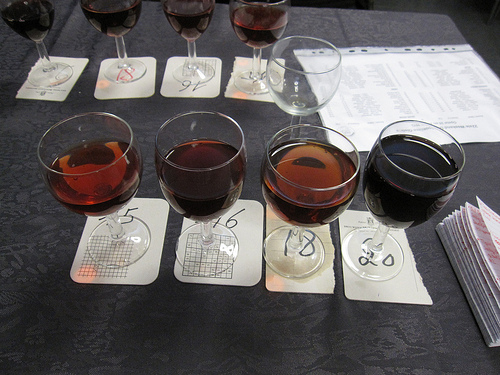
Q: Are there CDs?
A: No, there are no cds.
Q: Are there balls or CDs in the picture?
A: No, there are no CDs or balls.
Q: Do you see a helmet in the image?
A: No, there are no helmets.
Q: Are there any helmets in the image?
A: No, there are no helmets.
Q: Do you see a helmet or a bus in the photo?
A: No, there are no helmets or buses.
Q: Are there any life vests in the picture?
A: No, there are no life vests.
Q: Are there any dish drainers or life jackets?
A: No, there are no life jackets or dish drainers.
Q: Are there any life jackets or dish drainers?
A: No, there are no life jackets or dish drainers.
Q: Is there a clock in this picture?
A: No, there are no clocks.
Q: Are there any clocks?
A: No, there are no clocks.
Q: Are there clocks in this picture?
A: No, there are no clocks.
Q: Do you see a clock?
A: No, there are no clocks.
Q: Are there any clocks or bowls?
A: No, there are no clocks or bowls.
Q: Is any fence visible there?
A: No, there are no fences.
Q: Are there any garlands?
A: No, there are no garlands.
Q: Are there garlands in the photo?
A: No, there are no garlands.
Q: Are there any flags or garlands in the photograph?
A: No, there are no garlands or flags.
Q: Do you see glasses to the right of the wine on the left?
A: Yes, there are glasses to the right of the wine.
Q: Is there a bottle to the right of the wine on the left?
A: No, there are glasses to the right of the wine.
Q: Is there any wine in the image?
A: Yes, there is wine.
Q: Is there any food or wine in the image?
A: Yes, there is wine.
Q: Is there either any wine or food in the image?
A: Yes, there is wine.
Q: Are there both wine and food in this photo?
A: No, there is wine but no food.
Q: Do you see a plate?
A: No, there are no plates.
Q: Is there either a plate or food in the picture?
A: No, there are no plates or food.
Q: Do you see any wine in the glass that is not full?
A: Yes, there is wine in the glass.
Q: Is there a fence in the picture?
A: No, there are no fences.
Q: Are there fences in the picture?
A: No, there are no fences.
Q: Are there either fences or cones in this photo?
A: No, there are no fences or cones.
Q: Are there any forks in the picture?
A: No, there are no forks.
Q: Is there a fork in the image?
A: No, there are no forks.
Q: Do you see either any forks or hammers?
A: No, there are no forks or hammers.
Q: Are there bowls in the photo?
A: No, there are no bowls.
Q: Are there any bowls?
A: No, there are no bowls.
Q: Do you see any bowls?
A: No, there are no bowls.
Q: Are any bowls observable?
A: No, there are no bowls.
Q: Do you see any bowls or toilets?
A: No, there are no bowls or toilets.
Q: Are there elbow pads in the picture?
A: No, there are no elbow pads.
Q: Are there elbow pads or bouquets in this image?
A: No, there are no elbow pads or bouquets.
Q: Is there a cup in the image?
A: No, there are no cups.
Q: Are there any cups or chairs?
A: No, there are no cups or chairs.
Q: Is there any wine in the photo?
A: Yes, there is wine.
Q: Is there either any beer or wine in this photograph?
A: Yes, there is wine.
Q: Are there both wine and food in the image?
A: No, there is wine but no food.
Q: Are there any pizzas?
A: No, there are no pizzas.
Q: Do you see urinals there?
A: No, there are no urinals.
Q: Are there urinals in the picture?
A: No, there are no urinals.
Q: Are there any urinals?
A: No, there are no urinals.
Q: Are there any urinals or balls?
A: No, there are no urinals or balls.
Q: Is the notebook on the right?
A: Yes, the notebook is on the right of the image.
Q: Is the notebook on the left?
A: No, the notebook is on the right of the image.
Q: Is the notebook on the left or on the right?
A: The notebook is on the right of the image.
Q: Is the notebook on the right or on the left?
A: The notebook is on the right of the image.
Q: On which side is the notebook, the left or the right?
A: The notebook is on the right of the image.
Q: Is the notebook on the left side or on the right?
A: The notebook is on the right of the image.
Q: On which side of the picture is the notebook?
A: The notebook is on the right of the image.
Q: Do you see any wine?
A: Yes, there is wine.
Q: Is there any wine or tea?
A: Yes, there is wine.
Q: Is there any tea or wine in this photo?
A: Yes, there is wine.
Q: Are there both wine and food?
A: No, there is wine but no food.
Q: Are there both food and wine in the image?
A: No, there is wine but no food.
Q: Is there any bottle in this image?
A: No, there are no bottles.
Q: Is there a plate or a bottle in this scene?
A: No, there are no bottles or plates.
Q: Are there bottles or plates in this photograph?
A: No, there are no bottles or plates.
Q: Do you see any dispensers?
A: No, there are no dispensers.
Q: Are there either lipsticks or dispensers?
A: No, there are no dispensers or lipsticks.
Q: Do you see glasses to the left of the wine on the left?
A: Yes, there are glasses to the left of the wine.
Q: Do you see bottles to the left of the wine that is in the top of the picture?
A: No, there are glasses to the left of the wine.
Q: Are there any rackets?
A: No, there are no rackets.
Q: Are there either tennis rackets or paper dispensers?
A: No, there are no tennis rackets or paper dispensers.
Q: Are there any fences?
A: No, there are no fences.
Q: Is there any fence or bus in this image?
A: No, there are no fences or buses.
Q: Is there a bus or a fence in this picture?
A: No, there are no fences or buses.